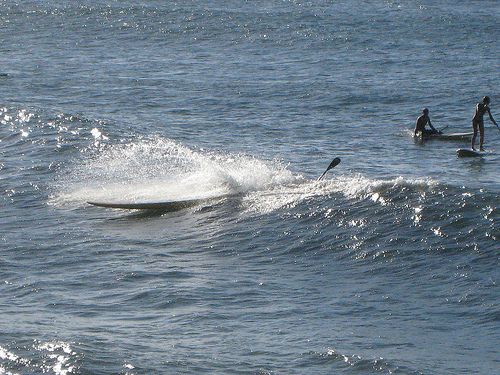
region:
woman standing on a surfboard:
[454, 95, 499, 157]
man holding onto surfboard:
[415, 108, 473, 142]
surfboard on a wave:
[90, 177, 244, 209]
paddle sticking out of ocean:
[315, 155, 343, 183]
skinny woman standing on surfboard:
[454, 95, 499, 154]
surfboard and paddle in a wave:
[83, 133, 340, 214]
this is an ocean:
[61, 12, 436, 282]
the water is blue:
[32, 27, 262, 238]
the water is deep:
[92, 35, 207, 136]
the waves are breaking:
[105, 135, 220, 231]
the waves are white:
[115, 145, 235, 230]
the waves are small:
[102, 235, 277, 325]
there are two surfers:
[385, 101, 495, 186]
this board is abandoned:
[112, 150, 332, 245]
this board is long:
[106, 156, 393, 260]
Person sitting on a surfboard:
[417, 105, 439, 137]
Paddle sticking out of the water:
[320, 158, 343, 178]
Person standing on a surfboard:
[464, 93, 495, 154]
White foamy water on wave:
[350, 176, 427, 193]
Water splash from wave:
[75, 137, 215, 186]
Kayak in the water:
[85, 190, 240, 213]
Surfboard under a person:
[456, 143, 488, 158]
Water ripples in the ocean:
[146, 262, 362, 335]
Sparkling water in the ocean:
[125, 5, 379, 50]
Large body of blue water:
[140, 41, 283, 128]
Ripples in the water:
[317, 192, 418, 265]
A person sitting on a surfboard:
[412, 98, 449, 148]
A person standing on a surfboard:
[456, 82, 494, 163]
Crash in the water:
[103, 115, 348, 226]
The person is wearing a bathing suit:
[470, 92, 495, 148]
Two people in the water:
[403, 78, 495, 155]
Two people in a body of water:
[402, 74, 492, 152]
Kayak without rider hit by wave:
[11, 135, 343, 212]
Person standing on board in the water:
[456, 94, 499, 158]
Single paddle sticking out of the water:
[318, 156, 343, 184]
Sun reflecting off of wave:
[281, 175, 499, 260]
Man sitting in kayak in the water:
[404, 107, 475, 139]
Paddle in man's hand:
[433, 123, 450, 134]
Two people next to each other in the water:
[413, 91, 498, 158]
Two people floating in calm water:
[3, 38, 498, 161]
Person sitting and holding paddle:
[411, 107, 475, 142]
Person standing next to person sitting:
[413, 95, 498, 159]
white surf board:
[84, 179, 249, 226]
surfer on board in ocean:
[411, 79, 448, 157]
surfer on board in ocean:
[463, 70, 497, 170]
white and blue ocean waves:
[94, 272, 140, 299]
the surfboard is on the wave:
[79, 169, 312, 217]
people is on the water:
[403, 83, 498, 166]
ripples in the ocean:
[78, 246, 379, 345]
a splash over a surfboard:
[71, 116, 302, 218]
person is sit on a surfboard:
[406, 103, 458, 147]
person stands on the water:
[452, 91, 497, 160]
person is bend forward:
[466, 86, 499, 153]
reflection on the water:
[463, 153, 495, 188]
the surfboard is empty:
[75, 183, 253, 219]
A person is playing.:
[475, 83, 493, 160]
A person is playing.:
[407, 99, 436, 144]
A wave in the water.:
[71, 127, 251, 254]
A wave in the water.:
[267, 165, 477, 257]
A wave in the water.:
[316, 327, 441, 372]